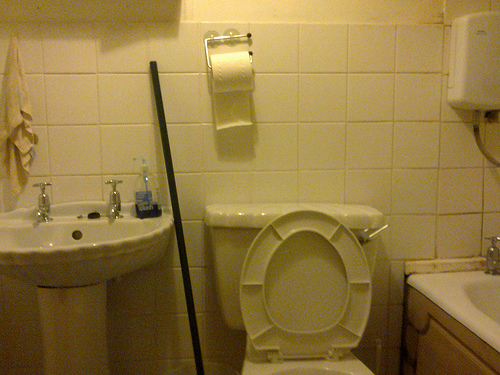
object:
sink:
[0, 200, 177, 289]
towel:
[0, 35, 40, 201]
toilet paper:
[209, 50, 255, 131]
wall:
[0, 0, 500, 373]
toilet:
[201, 198, 387, 375]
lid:
[202, 203, 386, 229]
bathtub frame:
[403, 286, 500, 375]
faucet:
[32, 182, 55, 223]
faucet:
[103, 178, 125, 220]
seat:
[239, 360, 374, 375]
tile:
[297, 122, 347, 171]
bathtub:
[401, 269, 500, 374]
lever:
[368, 224, 390, 241]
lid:
[237, 208, 375, 363]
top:
[202, 201, 386, 230]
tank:
[204, 202, 387, 333]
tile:
[345, 73, 395, 123]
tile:
[43, 73, 99, 126]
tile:
[93, 21, 150, 74]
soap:
[134, 201, 162, 219]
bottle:
[132, 156, 163, 219]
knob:
[31, 181, 53, 188]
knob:
[103, 179, 124, 185]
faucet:
[483, 235, 500, 275]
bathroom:
[0, 0, 498, 375]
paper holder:
[203, 32, 253, 69]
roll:
[208, 50, 256, 94]